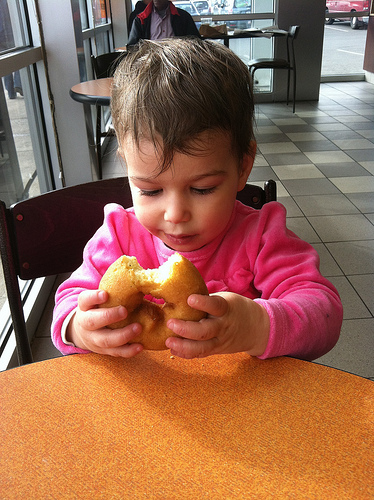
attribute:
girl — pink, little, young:
[51, 35, 344, 362]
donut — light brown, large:
[96, 251, 207, 352]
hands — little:
[73, 289, 262, 359]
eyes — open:
[135, 180, 220, 196]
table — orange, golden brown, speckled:
[2, 344, 372, 499]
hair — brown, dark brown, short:
[109, 32, 261, 173]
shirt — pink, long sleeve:
[49, 200, 343, 364]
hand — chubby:
[164, 289, 263, 360]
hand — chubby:
[72, 289, 143, 358]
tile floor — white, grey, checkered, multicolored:
[23, 79, 373, 382]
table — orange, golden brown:
[74, 72, 121, 180]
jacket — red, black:
[125, 3, 200, 42]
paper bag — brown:
[197, 22, 228, 40]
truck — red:
[322, 0, 371, 29]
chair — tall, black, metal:
[246, 23, 300, 113]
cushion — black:
[247, 56, 289, 68]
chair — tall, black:
[87, 48, 129, 179]